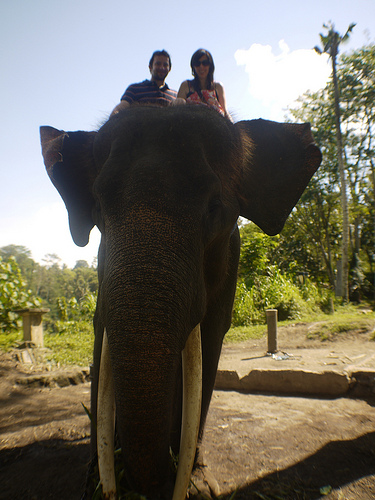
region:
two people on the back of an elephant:
[42, 31, 328, 416]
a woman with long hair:
[190, 46, 222, 94]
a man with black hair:
[137, 48, 173, 83]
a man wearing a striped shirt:
[114, 46, 178, 109]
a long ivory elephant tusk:
[173, 328, 211, 495]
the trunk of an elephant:
[106, 208, 181, 494]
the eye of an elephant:
[207, 189, 222, 218]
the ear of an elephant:
[235, 111, 321, 238]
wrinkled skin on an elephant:
[142, 234, 165, 292]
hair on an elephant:
[227, 121, 254, 189]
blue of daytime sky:
[2, 2, 370, 248]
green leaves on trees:
[1, 246, 92, 303]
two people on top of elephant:
[38, 46, 320, 498]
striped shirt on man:
[123, 81, 173, 106]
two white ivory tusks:
[95, 323, 203, 496]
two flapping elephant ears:
[37, 120, 322, 247]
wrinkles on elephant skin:
[110, 240, 190, 330]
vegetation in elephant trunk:
[97, 330, 187, 497]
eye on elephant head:
[206, 195, 223, 215]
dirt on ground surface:
[5, 385, 368, 496]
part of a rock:
[330, 372, 332, 376]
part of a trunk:
[190, 415, 193, 421]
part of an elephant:
[151, 384, 154, 393]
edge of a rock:
[286, 381, 292, 398]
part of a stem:
[312, 307, 317, 319]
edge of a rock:
[240, 381, 250, 393]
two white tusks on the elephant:
[95, 323, 202, 499]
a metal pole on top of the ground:
[265, 308, 278, 353]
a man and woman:
[109, 47, 231, 120]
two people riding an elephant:
[38, 47, 322, 498]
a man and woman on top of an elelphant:
[38, 48, 323, 499]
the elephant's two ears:
[39, 118, 322, 247]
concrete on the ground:
[221, 354, 374, 497]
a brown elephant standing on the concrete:
[38, 103, 323, 497]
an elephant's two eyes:
[91, 191, 220, 214]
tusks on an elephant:
[95, 324, 202, 499]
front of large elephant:
[52, 99, 243, 495]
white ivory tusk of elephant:
[158, 314, 208, 497]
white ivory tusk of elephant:
[81, 329, 156, 495]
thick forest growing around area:
[7, 217, 371, 348]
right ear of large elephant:
[24, 113, 100, 258]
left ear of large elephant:
[245, 119, 303, 221]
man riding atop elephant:
[123, 33, 179, 117]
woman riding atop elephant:
[177, 37, 220, 125]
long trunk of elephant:
[101, 195, 169, 498]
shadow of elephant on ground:
[17, 416, 96, 497]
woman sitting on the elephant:
[185, 46, 225, 111]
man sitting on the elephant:
[121, 46, 176, 103]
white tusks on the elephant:
[91, 322, 207, 492]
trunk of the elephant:
[89, 215, 194, 498]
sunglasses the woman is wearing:
[192, 56, 207, 66]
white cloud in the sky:
[212, 41, 335, 113]